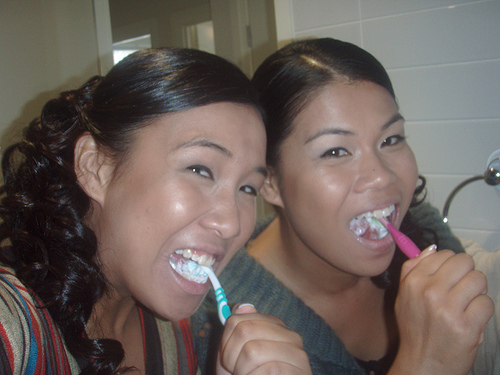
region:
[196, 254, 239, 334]
A blue and white tooth brush.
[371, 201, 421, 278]
A solid pink tooth brush.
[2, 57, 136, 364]
Long curly black hair on the girl.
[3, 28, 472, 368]
Two girls brushing their teeth.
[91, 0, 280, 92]
A doorway into the room.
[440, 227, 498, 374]
A white towel hanging on the wall.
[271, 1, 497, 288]
White tiles on the wall.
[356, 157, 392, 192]
A black mole on the girl's nose.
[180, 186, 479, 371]
A grey swear worn by the girl.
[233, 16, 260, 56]
The hinge for a white door.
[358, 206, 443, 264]
the toothbrush is orange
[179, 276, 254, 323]
the toothbrush is green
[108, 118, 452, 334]
they are two sisters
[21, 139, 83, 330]
she has long beautiful black hair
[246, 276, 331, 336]
the sweater is grey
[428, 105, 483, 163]
the wall is white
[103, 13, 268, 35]
the window is open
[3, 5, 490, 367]
the photo was taken indoors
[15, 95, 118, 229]
she has no earing on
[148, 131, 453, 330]
they are both smiling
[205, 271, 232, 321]
Blue and white toothbrush in girl's mouth.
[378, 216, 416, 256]
Pink toothbrush in girl's mouth.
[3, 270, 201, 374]
Striped shirt worn by the girl.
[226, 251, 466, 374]
Gray colored sweater worn by the girl.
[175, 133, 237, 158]
Left eyebrow of the girl on the left.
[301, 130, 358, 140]
Left eyebrow of the girl on the right.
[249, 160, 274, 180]
Right eyebrow of the girl on the left.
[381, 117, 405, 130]
Right eyebrow of the girl on the right.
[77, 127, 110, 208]
Left ear of the girl on the left.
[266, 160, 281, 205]
Left ear of the girl on the right.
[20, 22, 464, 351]
two Asian women brushing teeth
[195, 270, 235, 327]
blue and white toothbrush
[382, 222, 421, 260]
pink toothbrush handle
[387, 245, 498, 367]
left hand of a female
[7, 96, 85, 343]
curly ponytail of a female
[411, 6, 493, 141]
white tiled wall in bathroom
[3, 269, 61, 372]
striped top of a female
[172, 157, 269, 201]
eyes of an Asian woman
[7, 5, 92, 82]
beige painted wall of a bathroom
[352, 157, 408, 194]
nose of an Asian woman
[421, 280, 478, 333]
right hand of the lady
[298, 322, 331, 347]
part of a sweater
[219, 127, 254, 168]
head of the lady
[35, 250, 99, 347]
hair of a woman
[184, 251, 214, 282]
teeth of the lady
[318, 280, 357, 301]
neck of the lady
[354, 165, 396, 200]
nose of the lady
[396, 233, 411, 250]
part of the toothbrush handle